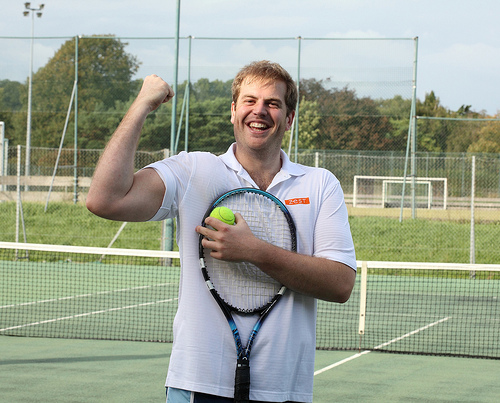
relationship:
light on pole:
[36, 0, 48, 12] [19, 1, 51, 205]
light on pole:
[32, 11, 42, 19] [19, 1, 51, 205]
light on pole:
[24, 2, 33, 9] [19, 1, 51, 205]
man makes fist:
[83, 57, 359, 402] [135, 69, 175, 110]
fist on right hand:
[135, 69, 175, 110] [136, 70, 177, 107]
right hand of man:
[136, 70, 177, 107] [83, 57, 359, 402]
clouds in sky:
[24, 42, 54, 67] [10, 7, 469, 89]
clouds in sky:
[323, 21, 387, 62] [4, 2, 496, 86]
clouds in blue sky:
[137, 42, 208, 71] [0, 0, 498, 118]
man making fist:
[83, 57, 359, 402] [135, 69, 175, 110]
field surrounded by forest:
[83, 96, 475, 371] [327, 93, 489, 155]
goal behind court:
[351, 172, 449, 210] [0, 260, 497, 402]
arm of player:
[84, 72, 190, 222] [84, 58, 357, 400]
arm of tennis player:
[256, 178, 363, 308] [80, 56, 359, 401]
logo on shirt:
[286, 195, 312, 210] [148, 146, 359, 401]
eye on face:
[244, 93, 255, 107] [233, 78, 291, 148]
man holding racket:
[84, 35, 389, 398] [185, 171, 310, 401]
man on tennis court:
[83, 57, 359, 402] [16, 242, 498, 399]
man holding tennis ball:
[83, 57, 359, 402] [207, 201, 239, 227]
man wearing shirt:
[183, 35, 360, 387] [148, 146, 359, 401]